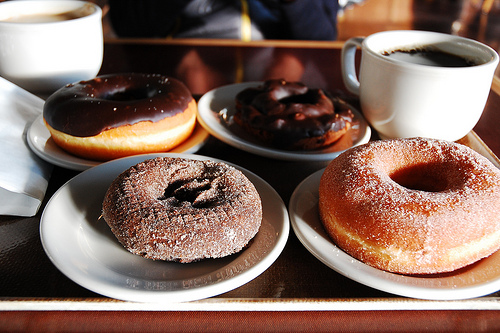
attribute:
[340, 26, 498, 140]
cup — white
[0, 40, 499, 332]
table — glass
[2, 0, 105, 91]
cup — white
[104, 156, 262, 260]
donut — powdered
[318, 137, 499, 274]
donut — powdered, sugar frosted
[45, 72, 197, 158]
donut — chocolate glazed, chocolate frosted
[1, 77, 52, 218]
napkin — white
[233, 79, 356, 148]
donut — chocolate frosted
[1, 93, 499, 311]
tray — brown